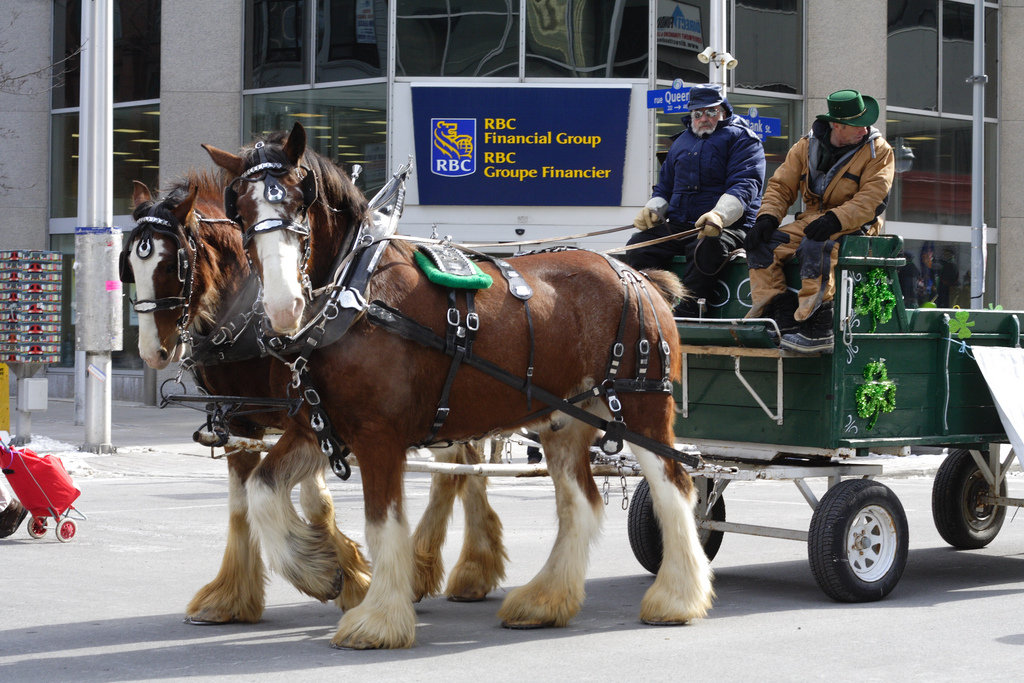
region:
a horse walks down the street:
[205, 115, 731, 641]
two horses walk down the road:
[106, 122, 735, 669]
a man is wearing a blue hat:
[676, 71, 738, 119]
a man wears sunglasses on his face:
[680, 90, 731, 133]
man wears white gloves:
[689, 190, 750, 241]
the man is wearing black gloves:
[742, 206, 791, 255]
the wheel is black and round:
[805, 472, 913, 608]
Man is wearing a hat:
[807, 74, 896, 144]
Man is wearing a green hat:
[810, 77, 886, 138]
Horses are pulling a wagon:
[111, 124, 797, 674]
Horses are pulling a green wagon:
[108, 111, 734, 665]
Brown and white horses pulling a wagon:
[115, 117, 755, 662]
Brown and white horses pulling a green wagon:
[115, 112, 741, 669]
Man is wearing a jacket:
[639, 111, 777, 249]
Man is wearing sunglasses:
[683, 93, 729, 125]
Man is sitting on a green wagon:
[621, 80, 761, 349]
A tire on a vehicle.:
[629, 471, 728, 583]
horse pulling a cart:
[202, 114, 718, 646]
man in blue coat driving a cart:
[629, 82, 795, 577]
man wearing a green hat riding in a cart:
[752, 89, 898, 337]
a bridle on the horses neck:
[199, 121, 415, 360]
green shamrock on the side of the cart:
[686, 233, 1022, 587]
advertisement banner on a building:
[382, 4, 645, 226]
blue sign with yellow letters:
[410, 83, 635, 205]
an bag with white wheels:
[0, 417, 91, 544]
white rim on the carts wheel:
[806, 480, 911, 602]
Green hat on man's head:
[810, 77, 891, 157]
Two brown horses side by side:
[102, 100, 732, 652]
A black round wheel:
[791, 459, 918, 611]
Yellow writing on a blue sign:
[399, 64, 641, 216]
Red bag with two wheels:
[0, 430, 95, 548]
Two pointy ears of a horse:
[190, 106, 317, 182]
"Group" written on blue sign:
[544, 111, 609, 156]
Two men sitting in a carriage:
[620, 51, 921, 374]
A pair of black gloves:
[734, 198, 855, 263]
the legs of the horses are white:
[197, 449, 719, 655]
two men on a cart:
[599, 59, 1022, 599]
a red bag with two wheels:
[6, 435, 97, 550]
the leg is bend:
[234, 424, 358, 615]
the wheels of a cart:
[618, 447, 1021, 603]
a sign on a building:
[398, 71, 643, 221]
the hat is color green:
[811, 82, 892, 132]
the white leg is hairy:
[325, 506, 434, 660]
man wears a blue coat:
[634, 80, 776, 284]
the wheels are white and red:
[19, 508, 83, 545]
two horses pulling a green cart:
[123, 119, 1019, 650]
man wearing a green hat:
[749, 85, 896, 333]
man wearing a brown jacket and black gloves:
[748, 91, 897, 354]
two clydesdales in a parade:
[118, 131, 716, 645]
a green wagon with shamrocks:
[617, 226, 1023, 460]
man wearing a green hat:
[813, 85, 886, 130]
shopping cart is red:
[3, 431, 88, 548]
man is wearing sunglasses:
[683, 100, 728, 125]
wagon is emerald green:
[589, 197, 1022, 448]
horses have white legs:
[192, 422, 722, 656]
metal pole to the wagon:
[191, 415, 759, 507]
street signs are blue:
[656, 74, 794, 147]